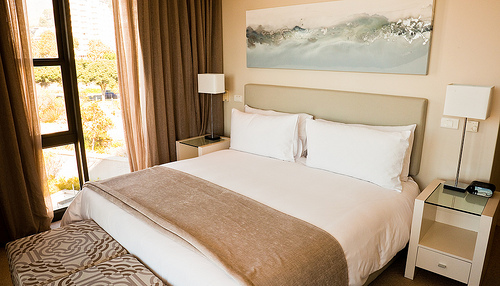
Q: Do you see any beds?
A: Yes, there is a bed.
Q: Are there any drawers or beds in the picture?
A: Yes, there is a bed.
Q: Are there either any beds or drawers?
A: Yes, there is a bed.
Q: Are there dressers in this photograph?
A: No, there are no dressers.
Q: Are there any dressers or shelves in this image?
A: No, there are no dressers or shelves.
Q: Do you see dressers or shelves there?
A: No, there are no dressers or shelves.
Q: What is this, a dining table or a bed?
A: This is a bed.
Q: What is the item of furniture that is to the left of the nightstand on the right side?
A: The piece of furniture is a bed.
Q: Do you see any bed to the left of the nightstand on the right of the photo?
A: Yes, there is a bed to the left of the nightstand.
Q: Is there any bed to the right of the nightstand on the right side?
A: No, the bed is to the left of the nightstand.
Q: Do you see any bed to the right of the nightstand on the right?
A: No, the bed is to the left of the nightstand.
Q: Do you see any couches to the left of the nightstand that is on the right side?
A: No, there is a bed to the left of the nightstand.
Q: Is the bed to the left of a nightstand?
A: Yes, the bed is to the left of a nightstand.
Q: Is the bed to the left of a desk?
A: No, the bed is to the left of a nightstand.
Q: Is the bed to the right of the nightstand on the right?
A: No, the bed is to the left of the nightstand.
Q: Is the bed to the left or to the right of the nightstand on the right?
A: The bed is to the left of the nightstand.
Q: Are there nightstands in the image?
A: Yes, there is a nightstand.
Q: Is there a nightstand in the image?
A: Yes, there is a nightstand.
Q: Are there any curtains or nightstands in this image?
A: Yes, there is a nightstand.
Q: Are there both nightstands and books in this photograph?
A: No, there is a nightstand but no books.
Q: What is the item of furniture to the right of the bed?
A: The piece of furniture is a nightstand.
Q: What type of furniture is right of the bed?
A: The piece of furniture is a nightstand.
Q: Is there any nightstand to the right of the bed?
A: Yes, there is a nightstand to the right of the bed.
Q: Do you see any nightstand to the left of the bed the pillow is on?
A: No, the nightstand is to the right of the bed.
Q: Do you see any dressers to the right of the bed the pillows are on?
A: No, there is a nightstand to the right of the bed.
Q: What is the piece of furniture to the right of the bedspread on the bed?
A: The piece of furniture is a nightstand.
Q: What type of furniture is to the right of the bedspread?
A: The piece of furniture is a nightstand.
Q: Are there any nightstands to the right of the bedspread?
A: Yes, there is a nightstand to the right of the bedspread.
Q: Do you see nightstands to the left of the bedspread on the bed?
A: No, the nightstand is to the right of the bedspread.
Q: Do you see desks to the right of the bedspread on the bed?
A: No, there is a nightstand to the right of the bedspread.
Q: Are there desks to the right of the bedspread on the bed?
A: No, there is a nightstand to the right of the bedspread.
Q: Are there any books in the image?
A: No, there are no books.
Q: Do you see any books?
A: No, there are no books.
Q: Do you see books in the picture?
A: No, there are no books.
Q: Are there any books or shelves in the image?
A: No, there are no books or shelves.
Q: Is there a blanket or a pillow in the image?
A: Yes, there is a pillow.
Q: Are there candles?
A: No, there are no candles.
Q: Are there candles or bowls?
A: No, there are no candles or bowls.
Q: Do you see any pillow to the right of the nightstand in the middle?
A: Yes, there is a pillow to the right of the nightstand.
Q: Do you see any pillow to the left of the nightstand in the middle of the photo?
A: No, the pillow is to the right of the nightstand.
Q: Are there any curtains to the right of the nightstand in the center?
A: No, there is a pillow to the right of the nightstand.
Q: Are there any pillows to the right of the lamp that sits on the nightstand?
A: Yes, there is a pillow to the right of the lamp.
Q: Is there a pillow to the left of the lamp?
A: No, the pillow is to the right of the lamp.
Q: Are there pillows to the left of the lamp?
A: No, the pillow is to the right of the lamp.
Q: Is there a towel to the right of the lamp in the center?
A: No, there is a pillow to the right of the lamp.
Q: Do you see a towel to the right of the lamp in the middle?
A: No, there is a pillow to the right of the lamp.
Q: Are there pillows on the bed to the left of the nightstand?
A: Yes, there is a pillow on the bed.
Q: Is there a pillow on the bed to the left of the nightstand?
A: Yes, there is a pillow on the bed.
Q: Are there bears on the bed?
A: No, there is a pillow on the bed.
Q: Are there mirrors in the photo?
A: No, there are no mirrors.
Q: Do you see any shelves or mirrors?
A: No, there are no mirrors or shelves.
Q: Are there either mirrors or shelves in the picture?
A: No, there are no mirrors or shelves.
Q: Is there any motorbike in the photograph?
A: No, there are no motorcycles.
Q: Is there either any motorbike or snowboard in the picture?
A: No, there are no motorcycles or snowboards.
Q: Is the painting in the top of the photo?
A: Yes, the painting is in the top of the image.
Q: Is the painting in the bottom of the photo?
A: No, the painting is in the top of the image.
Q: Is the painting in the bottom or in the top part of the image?
A: The painting is in the top of the image.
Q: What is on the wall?
A: The painting is on the wall.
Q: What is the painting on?
A: The painting is on the wall.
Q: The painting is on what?
A: The painting is on the wall.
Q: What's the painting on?
A: The painting is on the wall.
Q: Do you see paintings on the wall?
A: Yes, there is a painting on the wall.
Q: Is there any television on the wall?
A: No, there is a painting on the wall.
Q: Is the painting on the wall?
A: Yes, the painting is on the wall.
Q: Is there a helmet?
A: No, there are no helmets.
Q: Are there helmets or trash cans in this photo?
A: No, there are no helmets or trash cans.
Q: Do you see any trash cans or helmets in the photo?
A: No, there are no helmets or trash cans.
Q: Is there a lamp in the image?
A: Yes, there is a lamp.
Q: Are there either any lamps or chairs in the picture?
A: Yes, there is a lamp.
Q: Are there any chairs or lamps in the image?
A: Yes, there is a lamp.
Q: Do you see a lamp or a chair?
A: Yes, there is a lamp.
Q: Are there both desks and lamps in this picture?
A: No, there is a lamp but no desks.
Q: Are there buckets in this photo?
A: No, there are no buckets.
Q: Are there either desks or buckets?
A: No, there are no buckets or desks.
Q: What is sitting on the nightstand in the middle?
A: The lamp is sitting on the nightstand.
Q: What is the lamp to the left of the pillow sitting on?
A: The lamp is sitting on the nightstand.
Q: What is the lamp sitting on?
A: The lamp is sitting on the nightstand.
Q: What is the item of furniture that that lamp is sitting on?
A: The piece of furniture is a nightstand.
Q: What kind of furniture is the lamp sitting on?
A: The lamp is sitting on the nightstand.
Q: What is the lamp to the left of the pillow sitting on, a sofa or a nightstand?
A: The lamp is sitting on a nightstand.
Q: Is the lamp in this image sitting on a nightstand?
A: Yes, the lamp is sitting on a nightstand.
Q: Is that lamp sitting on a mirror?
A: No, the lamp is sitting on a nightstand.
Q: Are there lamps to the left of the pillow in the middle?
A: Yes, there is a lamp to the left of the pillow.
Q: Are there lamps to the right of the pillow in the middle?
A: No, the lamp is to the left of the pillow.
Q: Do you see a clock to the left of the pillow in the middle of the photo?
A: No, there is a lamp to the left of the pillow.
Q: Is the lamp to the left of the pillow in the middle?
A: Yes, the lamp is to the left of the pillow.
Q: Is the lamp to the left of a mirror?
A: No, the lamp is to the left of the pillow.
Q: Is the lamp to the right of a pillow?
A: No, the lamp is to the left of a pillow.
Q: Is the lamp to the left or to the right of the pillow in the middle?
A: The lamp is to the left of the pillow.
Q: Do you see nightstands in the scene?
A: Yes, there is a nightstand.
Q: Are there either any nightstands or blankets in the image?
A: Yes, there is a nightstand.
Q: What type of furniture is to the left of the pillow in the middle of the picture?
A: The piece of furniture is a nightstand.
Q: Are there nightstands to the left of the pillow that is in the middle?
A: Yes, there is a nightstand to the left of the pillow.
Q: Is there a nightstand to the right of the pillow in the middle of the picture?
A: No, the nightstand is to the left of the pillow.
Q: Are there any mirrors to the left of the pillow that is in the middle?
A: No, there is a nightstand to the left of the pillow.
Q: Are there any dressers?
A: No, there are no dressers.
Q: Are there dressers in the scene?
A: No, there are no dressers.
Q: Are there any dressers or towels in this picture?
A: No, there are no dressers or towels.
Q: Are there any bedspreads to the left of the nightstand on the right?
A: Yes, there is a bedspread to the left of the nightstand.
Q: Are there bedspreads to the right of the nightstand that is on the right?
A: No, the bedspread is to the left of the nightstand.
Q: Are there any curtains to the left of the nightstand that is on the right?
A: No, there is a bedspread to the left of the nightstand.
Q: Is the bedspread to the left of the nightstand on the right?
A: Yes, the bedspread is to the left of the nightstand.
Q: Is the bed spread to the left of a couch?
A: No, the bed spread is to the left of the nightstand.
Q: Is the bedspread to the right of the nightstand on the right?
A: No, the bedspread is to the left of the nightstand.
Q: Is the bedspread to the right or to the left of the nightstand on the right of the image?
A: The bedspread is to the left of the nightstand.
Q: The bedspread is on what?
A: The bedspread is on the bed.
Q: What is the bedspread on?
A: The bedspread is on the bed.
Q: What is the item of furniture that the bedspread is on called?
A: The piece of furniture is a bed.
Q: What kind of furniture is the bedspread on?
A: The bedspread is on the bed.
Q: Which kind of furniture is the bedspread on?
A: The bedspread is on the bed.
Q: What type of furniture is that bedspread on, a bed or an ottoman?
A: The bedspread is on a bed.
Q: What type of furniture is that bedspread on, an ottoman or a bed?
A: The bedspread is on a bed.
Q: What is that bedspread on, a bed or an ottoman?
A: The bedspread is on a bed.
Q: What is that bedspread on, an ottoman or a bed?
A: The bedspread is on a bed.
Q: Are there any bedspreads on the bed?
A: Yes, there is a bedspread on the bed.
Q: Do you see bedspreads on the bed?
A: Yes, there is a bedspread on the bed.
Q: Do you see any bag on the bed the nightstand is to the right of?
A: No, there is a bedspread on the bed.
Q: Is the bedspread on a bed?
A: Yes, the bedspread is on a bed.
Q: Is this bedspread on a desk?
A: No, the bedspread is on a bed.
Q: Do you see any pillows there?
A: Yes, there are pillows.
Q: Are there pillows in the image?
A: Yes, there are pillows.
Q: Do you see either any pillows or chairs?
A: Yes, there are pillows.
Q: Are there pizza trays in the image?
A: No, there are no pizza trays.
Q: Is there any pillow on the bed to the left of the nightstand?
A: Yes, there are pillows on the bed.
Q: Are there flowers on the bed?
A: No, there are pillows on the bed.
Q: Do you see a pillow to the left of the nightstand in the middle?
A: No, the pillows are to the right of the nightstand.